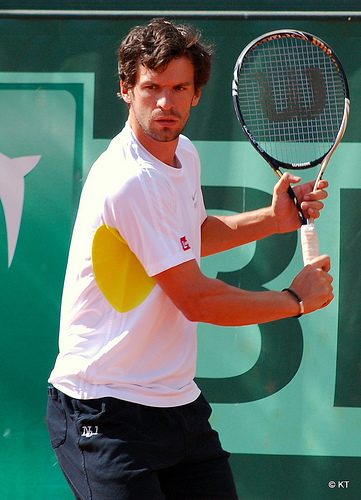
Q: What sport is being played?
A: Tennis.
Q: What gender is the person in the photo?
A: Male.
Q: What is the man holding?
A: A tennis racket.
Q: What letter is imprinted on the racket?
A: W.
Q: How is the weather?
A: Sunny.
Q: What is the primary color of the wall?
A: Green.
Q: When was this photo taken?
A: In the daytime.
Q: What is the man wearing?
A: T shirt and shorts.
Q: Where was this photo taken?
A: On tennis court.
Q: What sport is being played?
A: Tennis.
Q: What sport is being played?
A: Tennis.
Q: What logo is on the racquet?
A: Wilson.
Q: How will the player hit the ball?
A: With tennis racquet.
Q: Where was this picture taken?
A: A tennis court.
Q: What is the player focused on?
A: The ball.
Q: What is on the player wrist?
A: A bracelet.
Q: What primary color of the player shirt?
A: White.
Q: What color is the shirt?
A: Yellow and white.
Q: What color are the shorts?
A: Black.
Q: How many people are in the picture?
A: One.